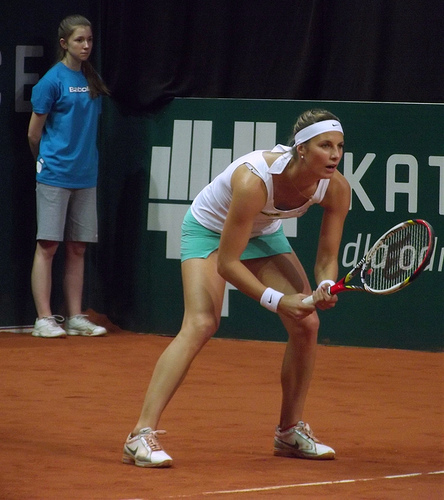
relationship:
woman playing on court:
[115, 109, 354, 471] [2, 328, 440, 498]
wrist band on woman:
[260, 287, 284, 310] [130, 63, 373, 498]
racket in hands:
[343, 217, 434, 296] [257, 272, 347, 327]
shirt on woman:
[29, 59, 104, 190] [33, 12, 111, 354]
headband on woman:
[295, 118, 346, 147] [115, 109, 354, 471]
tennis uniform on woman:
[187, 220, 296, 261] [127, 98, 396, 459]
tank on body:
[183, 145, 332, 244] [231, 155, 342, 455]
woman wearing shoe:
[115, 109, 354, 471] [128, 416, 185, 474]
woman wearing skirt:
[115, 109, 354, 471] [173, 205, 273, 263]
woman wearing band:
[115, 109, 354, 471] [260, 288, 285, 308]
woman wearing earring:
[115, 109, 354, 471] [298, 155, 307, 160]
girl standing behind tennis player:
[26, 12, 109, 341] [116, 105, 436, 470]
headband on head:
[274, 118, 345, 154] [287, 105, 349, 179]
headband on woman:
[274, 118, 345, 154] [127, 105, 353, 464]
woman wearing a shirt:
[25, 10, 109, 340] [18, 52, 106, 201]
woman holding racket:
[116, 91, 390, 470] [343, 217, 434, 296]